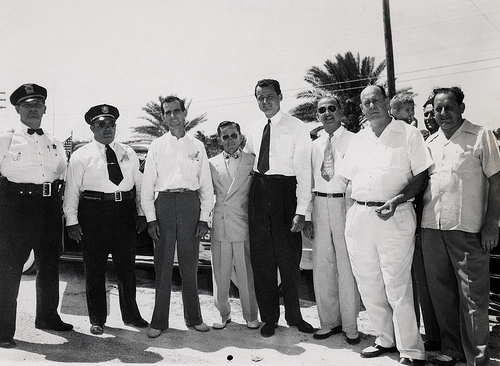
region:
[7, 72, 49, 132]
Face of man with cap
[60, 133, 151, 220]
Black tie with white shirt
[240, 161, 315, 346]
Black slacks on tall man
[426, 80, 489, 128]
Face of man on the right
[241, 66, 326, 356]
Tall man in the center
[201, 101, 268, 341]
Short man dressed in suite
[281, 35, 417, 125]
Trees in back of group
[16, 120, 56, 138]
Bowtie of man on the left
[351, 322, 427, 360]
Black and white shoes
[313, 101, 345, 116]
Sunglasses on man sixth from the left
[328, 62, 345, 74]
leaves of a tree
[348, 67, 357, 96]
section of a palm tree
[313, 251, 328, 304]
right leg of a man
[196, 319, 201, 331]
left foot of a man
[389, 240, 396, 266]
section of a white trouser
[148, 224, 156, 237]
right hand of a man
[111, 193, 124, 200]
section of a man's belt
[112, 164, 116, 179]
part of a black tie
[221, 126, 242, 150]
face of a man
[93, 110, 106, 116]
cap of a old man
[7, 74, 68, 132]
Man wearing hat on head.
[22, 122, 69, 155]
Man wearing black bow tie.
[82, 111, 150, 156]
Man wearing glasses on face.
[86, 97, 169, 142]
Man wearing hat on head.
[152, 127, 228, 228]
Man wearing white shirt.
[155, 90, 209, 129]
Man has dark hair.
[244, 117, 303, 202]
Man is wearing dark tie.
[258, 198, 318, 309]
Man has dark pants on.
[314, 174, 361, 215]
Man is wearing dark belt.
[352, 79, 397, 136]
Man is going bald.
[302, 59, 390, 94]
top of palm tree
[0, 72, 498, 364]
group of men posing for a photo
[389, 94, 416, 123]
face of a small boy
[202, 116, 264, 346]
short man in a suite wearing sunglasses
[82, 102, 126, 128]
hat of police officer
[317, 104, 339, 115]
sunglasses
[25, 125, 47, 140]
bow tie on a man's collard shirt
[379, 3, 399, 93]
wooden electrical pole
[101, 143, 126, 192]
man's neck tie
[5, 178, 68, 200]
belt to hold up pants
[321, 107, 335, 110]
section of sun glasses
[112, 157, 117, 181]
section of a black tie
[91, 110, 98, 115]
section of a cap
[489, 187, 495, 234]
left arm of a man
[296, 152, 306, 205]
left hand of a man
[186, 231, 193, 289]
left leg of a man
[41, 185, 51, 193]
section of a belts buckle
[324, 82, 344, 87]
leaves of a palm tree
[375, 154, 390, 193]
section of a white shirt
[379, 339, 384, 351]
right foot of a man